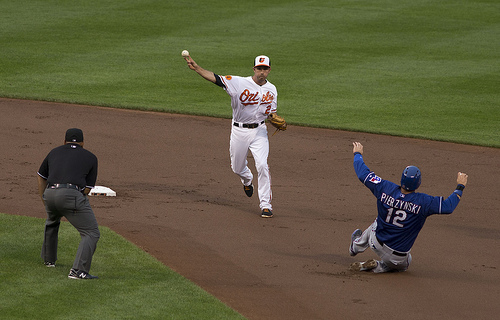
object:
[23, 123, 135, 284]
umpire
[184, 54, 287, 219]
player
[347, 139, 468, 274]
player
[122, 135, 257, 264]
dirt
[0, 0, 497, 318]
field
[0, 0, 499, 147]
grass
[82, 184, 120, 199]
base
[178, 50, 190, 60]
ball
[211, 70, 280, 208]
uniform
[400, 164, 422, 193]
helmet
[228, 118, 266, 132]
belt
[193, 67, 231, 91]
arm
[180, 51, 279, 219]
man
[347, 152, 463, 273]
uniform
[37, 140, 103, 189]
shirt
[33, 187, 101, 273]
pants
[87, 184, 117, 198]
plate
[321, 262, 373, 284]
footprint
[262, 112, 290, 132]
glove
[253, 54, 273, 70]
cap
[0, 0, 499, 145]
outfield